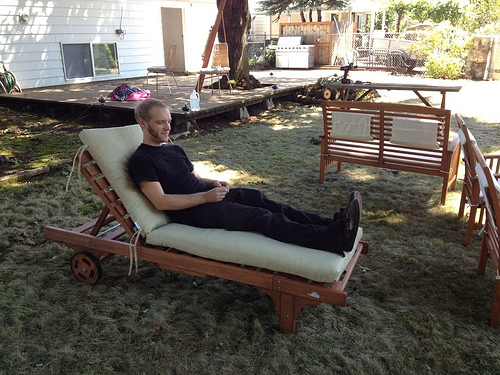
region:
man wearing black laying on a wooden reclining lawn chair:
[45, 96, 378, 333]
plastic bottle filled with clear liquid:
[186, 82, 204, 112]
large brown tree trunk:
[215, 2, 260, 89]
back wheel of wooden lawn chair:
[65, 249, 105, 284]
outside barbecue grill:
[266, 34, 314, 68]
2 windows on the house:
[54, 42, 129, 81]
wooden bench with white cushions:
[320, 97, 456, 204]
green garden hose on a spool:
[0, 63, 22, 93]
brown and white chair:
[144, 40, 181, 95]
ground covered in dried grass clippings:
[20, 287, 248, 374]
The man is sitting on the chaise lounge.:
[26, 83, 388, 330]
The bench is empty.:
[307, 75, 467, 215]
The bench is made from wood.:
[310, 82, 470, 202]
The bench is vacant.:
[303, 85, 468, 206]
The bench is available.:
[307, 83, 471, 215]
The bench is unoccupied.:
[303, 81, 471, 209]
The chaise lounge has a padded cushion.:
[12, 75, 387, 353]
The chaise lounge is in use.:
[28, 88, 387, 338]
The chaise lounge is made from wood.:
[31, 79, 392, 349]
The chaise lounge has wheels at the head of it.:
[21, 84, 383, 350]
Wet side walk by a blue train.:
[342, 368, 363, 374]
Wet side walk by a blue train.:
[174, 68, 198, 106]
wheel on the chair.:
[70, 254, 97, 290]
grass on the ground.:
[132, 318, 162, 347]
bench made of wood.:
[388, 155, 419, 162]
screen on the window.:
[70, 50, 87, 69]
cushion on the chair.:
[227, 243, 258, 253]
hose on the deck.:
[3, 76, 13, 84]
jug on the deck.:
[188, 88, 200, 108]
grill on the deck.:
[277, 48, 312, 63]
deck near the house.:
[68, 88, 90, 99]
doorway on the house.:
[168, 16, 180, 43]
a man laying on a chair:
[42, 95, 372, 339]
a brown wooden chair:
[45, 113, 369, 345]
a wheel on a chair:
[68, 245, 100, 285]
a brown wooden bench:
[310, 85, 466, 206]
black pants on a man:
[171, 185, 369, 266]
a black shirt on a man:
[128, 133, 210, 217]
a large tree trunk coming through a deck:
[213, 2, 265, 93]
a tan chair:
[138, 37, 182, 99]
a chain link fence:
[234, 23, 445, 73]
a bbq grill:
[271, 28, 321, 71]